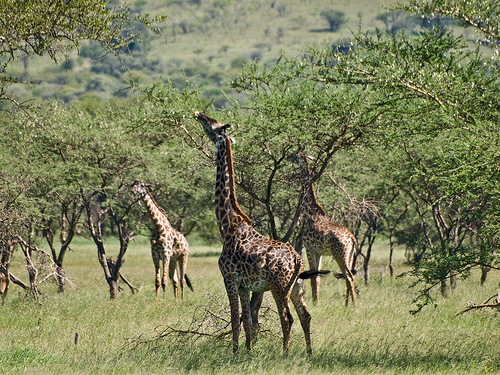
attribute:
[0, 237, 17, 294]
trunk — Tree 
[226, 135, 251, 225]
mane — brown giraffe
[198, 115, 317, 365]
giraffe — One 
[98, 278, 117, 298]
trunk — tree   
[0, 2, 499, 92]
hill — distance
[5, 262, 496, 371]
grass — Green 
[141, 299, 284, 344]
fallen branches — fallen  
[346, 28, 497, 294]
trees — green 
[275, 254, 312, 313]
giraffe tail — giraffe 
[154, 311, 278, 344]
branch — Tree  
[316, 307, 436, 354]
grass — green 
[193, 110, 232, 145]
giraffe head — giraffe , top 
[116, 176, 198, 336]
giraffe — Three 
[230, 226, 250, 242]
spot — brown 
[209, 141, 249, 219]
neck — long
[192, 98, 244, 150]
head — large 